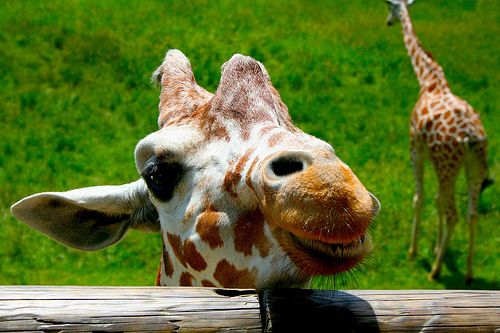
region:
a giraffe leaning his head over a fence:
[3, 34, 403, 304]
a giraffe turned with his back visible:
[381, 0, 488, 282]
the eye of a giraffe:
[136, 156, 189, 203]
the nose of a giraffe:
[258, 138, 385, 223]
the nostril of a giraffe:
[263, 155, 308, 182]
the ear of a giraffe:
[6, 178, 147, 265]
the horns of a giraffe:
[129, 40, 296, 107]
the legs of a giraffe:
[398, 165, 499, 279]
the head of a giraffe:
[378, 0, 413, 32]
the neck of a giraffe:
[401, 18, 451, 88]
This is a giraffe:
[13, 33, 388, 310]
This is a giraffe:
[10, 36, 414, 329]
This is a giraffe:
[14, 45, 394, 314]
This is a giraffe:
[0, 45, 390, 319]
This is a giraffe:
[10, 47, 391, 299]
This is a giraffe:
[361, 2, 498, 212]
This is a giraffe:
[14, 38, 380, 309]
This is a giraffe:
[10, 41, 405, 293]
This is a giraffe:
[16, 41, 386, 331]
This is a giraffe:
[378, 7, 498, 312]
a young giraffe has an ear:
[6, 175, 139, 258]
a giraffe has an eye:
[112, 132, 197, 209]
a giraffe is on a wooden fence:
[5, 24, 382, 302]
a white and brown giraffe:
[10, 29, 378, 294]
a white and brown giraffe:
[374, 2, 491, 287]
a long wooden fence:
[21, 278, 487, 326]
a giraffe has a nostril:
[257, 144, 321, 180]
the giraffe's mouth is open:
[265, 164, 387, 289]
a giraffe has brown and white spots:
[427, 122, 463, 178]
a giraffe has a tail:
[470, 129, 494, 206]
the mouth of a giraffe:
[265, 194, 391, 286]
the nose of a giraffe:
[247, 127, 357, 189]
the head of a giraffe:
[8, 49, 380, 293]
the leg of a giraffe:
[399, 174, 426, 263]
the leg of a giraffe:
[463, 194, 479, 283]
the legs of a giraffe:
[430, 194, 460, 281]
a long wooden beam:
[0, 282, 497, 329]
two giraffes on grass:
[7, 2, 490, 292]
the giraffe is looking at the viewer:
[17, 47, 380, 298]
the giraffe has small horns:
[154, 40, 282, 125]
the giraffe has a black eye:
[141, 156, 170, 201]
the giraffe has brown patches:
[148, 48, 377, 290]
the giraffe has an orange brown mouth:
[273, 162, 376, 277]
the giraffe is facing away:
[376, 0, 488, 275]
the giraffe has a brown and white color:
[382, 2, 499, 282]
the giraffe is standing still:
[381, 6, 496, 287]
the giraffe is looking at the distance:
[378, 2, 485, 282]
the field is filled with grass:
[1, 1, 493, 318]